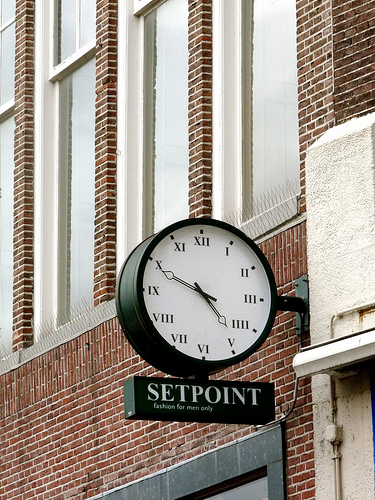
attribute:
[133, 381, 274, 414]
sign —  setpoint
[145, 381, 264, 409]
letters — White , setpoint"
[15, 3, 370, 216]
building — side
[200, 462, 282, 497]
glass — pane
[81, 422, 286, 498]
trim — Black slate door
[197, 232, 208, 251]
roman numeral — 12, black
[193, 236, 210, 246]
roman numberal — 10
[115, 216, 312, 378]
clock — dark green 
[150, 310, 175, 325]
roman numeral — 8,  black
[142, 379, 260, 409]
setpoint — word 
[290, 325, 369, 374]
frame — top, door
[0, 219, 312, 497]
wall — brick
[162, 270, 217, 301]
hand — long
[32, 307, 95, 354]
sill — white window 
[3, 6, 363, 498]
building — bricks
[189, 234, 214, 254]
numerals — 12, roman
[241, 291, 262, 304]
numerals — 3, roman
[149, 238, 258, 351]
numerals —  Roman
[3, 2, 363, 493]
building. — brick , side 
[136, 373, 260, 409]
word — men 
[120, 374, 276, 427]
sign —  reads , setpoint , dark green 